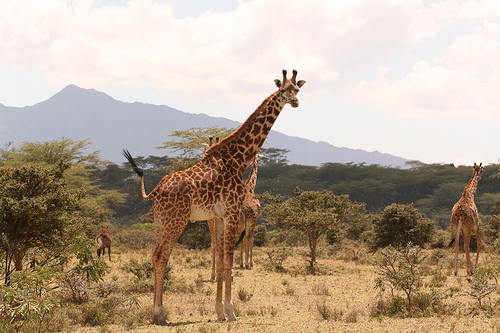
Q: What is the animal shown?
A: A giraffe.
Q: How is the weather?
A: Cloudy.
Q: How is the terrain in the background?
A: Mountainous.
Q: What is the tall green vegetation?
A: Trees.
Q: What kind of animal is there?
A: Giraffe.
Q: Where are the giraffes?
A: In the wild.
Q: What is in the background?
A: Mountains.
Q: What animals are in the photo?
A: Giraffes.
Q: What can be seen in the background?
A: A mountain.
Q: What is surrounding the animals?
A: Trees.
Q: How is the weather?
A: Cloudy.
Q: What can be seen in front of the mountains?
A: A forest.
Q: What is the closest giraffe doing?
A: Facing the camera.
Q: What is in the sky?
A: Clouds.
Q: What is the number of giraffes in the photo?
A: Four.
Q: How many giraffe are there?
A: 3.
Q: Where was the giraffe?
A: In the field.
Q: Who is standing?
A: The griffes.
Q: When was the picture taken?
A: In the daytime.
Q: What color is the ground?
A: Brown.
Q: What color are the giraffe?
A: Spotted tan.